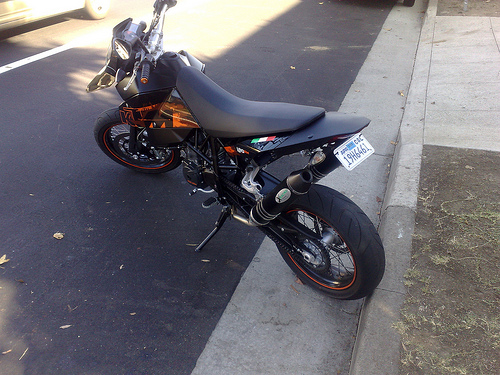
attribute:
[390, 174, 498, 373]
grass — dead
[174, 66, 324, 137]
seat — black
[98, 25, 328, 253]
bike — black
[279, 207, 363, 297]
rim — orange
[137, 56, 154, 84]
handlebar — orange